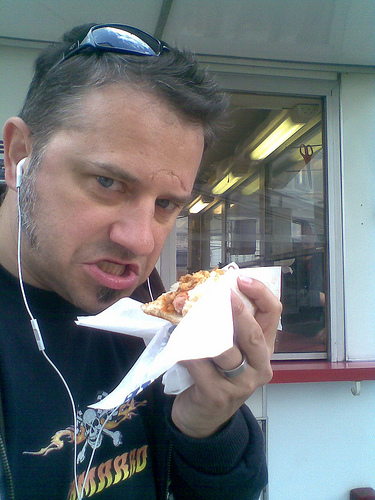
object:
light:
[189, 199, 211, 214]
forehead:
[71, 83, 209, 186]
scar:
[148, 166, 191, 192]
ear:
[6, 116, 31, 186]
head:
[2, 21, 223, 324]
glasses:
[62, 25, 174, 69]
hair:
[20, 24, 228, 163]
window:
[75, 64, 333, 363]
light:
[250, 103, 328, 164]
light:
[213, 168, 250, 198]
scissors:
[295, 141, 319, 191]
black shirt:
[0, 281, 269, 495]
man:
[275, 216, 334, 343]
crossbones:
[71, 405, 124, 467]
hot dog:
[140, 270, 216, 326]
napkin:
[61, 262, 282, 412]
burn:
[16, 139, 44, 232]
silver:
[215, 353, 249, 380]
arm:
[280, 285, 331, 311]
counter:
[267, 363, 365, 387]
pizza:
[147, 260, 257, 323]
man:
[0, 17, 287, 500]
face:
[25, 90, 208, 315]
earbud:
[15, 154, 29, 187]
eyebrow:
[161, 191, 196, 201]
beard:
[96, 286, 119, 304]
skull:
[74, 399, 123, 452]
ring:
[217, 354, 249, 379]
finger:
[183, 361, 235, 410]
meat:
[163, 267, 213, 317]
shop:
[146, 50, 349, 337]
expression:
[294, 238, 317, 259]